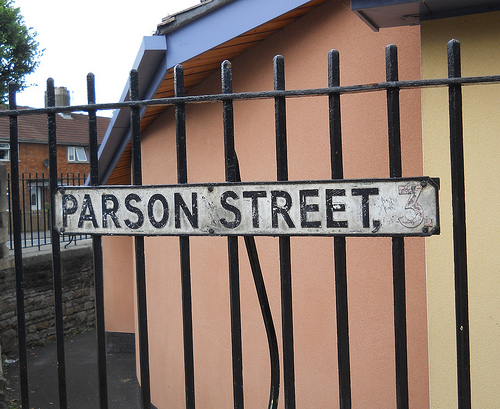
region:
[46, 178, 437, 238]
the sign parson street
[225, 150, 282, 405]
the bent bar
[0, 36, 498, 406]
the iron fence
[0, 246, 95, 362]
the brick wall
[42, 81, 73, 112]
the chimney on roof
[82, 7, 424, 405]
peach wall on building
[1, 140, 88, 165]
opened windows on building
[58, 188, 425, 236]
a sign on the gate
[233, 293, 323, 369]
the gate is black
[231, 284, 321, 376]
a gate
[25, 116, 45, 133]
the roof on the building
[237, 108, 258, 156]
the home is pink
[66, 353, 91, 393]
the ground is grey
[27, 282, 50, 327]
a wall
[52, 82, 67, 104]
chimney on the building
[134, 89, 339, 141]
a black gate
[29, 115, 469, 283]
this is a sign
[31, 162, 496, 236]
the sign is white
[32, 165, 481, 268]
black writing on sign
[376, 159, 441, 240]
faded number on sign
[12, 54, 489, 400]
sign attached to a fence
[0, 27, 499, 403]
fence is cast iron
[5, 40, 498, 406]
iron fence is black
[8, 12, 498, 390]
vertical rods on fence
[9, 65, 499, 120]
horizontal pole on fence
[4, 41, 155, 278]
brick house in background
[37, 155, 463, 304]
a street sign on fence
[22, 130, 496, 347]
street sign on a metal fence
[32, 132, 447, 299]
a street sign on a metal fence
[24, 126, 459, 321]
street sign on a black fence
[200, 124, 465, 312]
a black metal fence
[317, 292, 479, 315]
black metal fence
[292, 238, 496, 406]
a black metal fence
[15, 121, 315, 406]
a black metal fence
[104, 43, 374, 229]
a black metal fence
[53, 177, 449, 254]
The sign saying parson street.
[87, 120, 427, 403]
The peach house behind the gate.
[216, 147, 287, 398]
The bended black bar.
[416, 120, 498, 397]
The tan wall next to the house.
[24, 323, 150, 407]
The portion of the ground that is paved.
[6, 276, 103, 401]
The rock wall.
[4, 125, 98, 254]
The brick house.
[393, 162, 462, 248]
The number 3 on the sign.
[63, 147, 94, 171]
The top window on the brick house.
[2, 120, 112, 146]
The brown roof on the brick house.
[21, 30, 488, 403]
sign on a fence